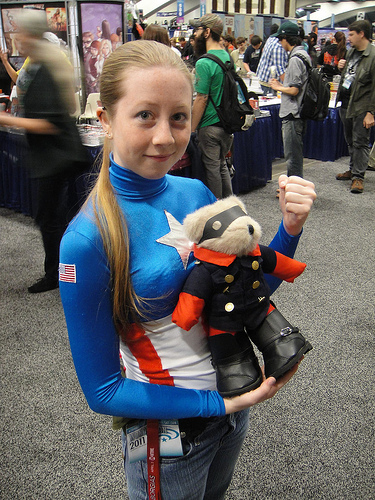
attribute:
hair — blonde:
[87, 37, 191, 324]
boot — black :
[202, 329, 264, 398]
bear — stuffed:
[170, 194, 311, 398]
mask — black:
[198, 204, 247, 244]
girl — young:
[81, 38, 244, 284]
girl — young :
[59, 51, 228, 408]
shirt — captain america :
[72, 179, 291, 422]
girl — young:
[46, 37, 319, 497]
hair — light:
[86, 37, 194, 346]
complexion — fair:
[120, 73, 160, 167]